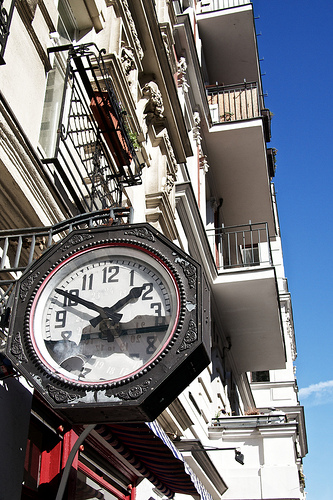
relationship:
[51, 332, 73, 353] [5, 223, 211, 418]
number on clock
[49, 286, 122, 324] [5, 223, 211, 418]
hand of clock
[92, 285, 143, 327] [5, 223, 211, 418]
hand of clock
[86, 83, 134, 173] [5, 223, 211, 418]
flower box above clock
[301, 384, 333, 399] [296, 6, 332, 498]
cloud in sky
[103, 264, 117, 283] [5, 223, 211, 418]
number on clock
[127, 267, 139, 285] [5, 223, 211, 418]
number on clock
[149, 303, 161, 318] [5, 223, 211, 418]
number on clock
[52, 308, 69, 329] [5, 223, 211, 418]
number on clock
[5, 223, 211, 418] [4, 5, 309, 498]
clock on building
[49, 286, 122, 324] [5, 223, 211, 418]
hand on clock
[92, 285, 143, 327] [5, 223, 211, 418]
hand on clock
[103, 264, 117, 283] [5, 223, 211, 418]
12 on clock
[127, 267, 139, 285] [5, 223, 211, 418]
1 on clock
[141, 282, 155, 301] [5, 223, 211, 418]
number on clock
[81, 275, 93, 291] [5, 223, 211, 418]
number on clock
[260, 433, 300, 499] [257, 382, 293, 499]
part of pillar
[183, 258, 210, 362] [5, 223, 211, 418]
edge of clock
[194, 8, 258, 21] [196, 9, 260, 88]
edge of roof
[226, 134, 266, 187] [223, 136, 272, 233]
part of surface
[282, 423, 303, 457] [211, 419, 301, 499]
part of wall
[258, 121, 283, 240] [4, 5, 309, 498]
edge of building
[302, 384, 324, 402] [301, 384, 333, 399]
part of cloud